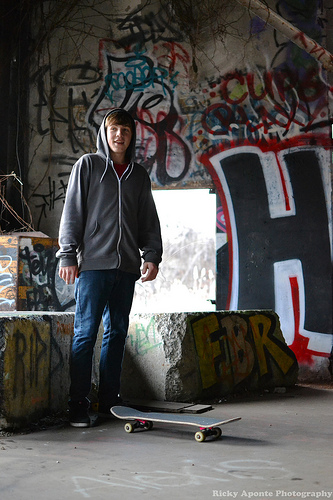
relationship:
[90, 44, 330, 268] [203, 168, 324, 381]
walls covered in grafitti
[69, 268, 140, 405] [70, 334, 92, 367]
jeans wrinkled at knee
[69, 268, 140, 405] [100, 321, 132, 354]
jeans wrinkled at knee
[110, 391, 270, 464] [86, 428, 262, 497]
skateboard on ground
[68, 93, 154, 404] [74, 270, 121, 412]
boy wearing jeans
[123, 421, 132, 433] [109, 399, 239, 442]
wheels on skateboard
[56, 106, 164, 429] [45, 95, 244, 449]
boy about to skate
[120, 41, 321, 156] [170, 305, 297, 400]
graffiti on wall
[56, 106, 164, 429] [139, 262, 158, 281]
boy has hand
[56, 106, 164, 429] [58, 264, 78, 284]
boy has hand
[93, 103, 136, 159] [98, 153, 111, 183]
hood has string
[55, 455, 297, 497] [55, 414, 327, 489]
alexis on ground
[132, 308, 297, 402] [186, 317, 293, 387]
concrete has graffiti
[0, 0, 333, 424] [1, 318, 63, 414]
concrete has graffiti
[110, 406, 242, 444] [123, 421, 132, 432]
skateboard with wheel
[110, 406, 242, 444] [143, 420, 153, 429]
skateboard with wheel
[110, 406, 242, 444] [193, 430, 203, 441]
skateboard with wheel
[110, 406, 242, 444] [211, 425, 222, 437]
skateboard with wheel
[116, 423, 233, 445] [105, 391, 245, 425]
wheels of board